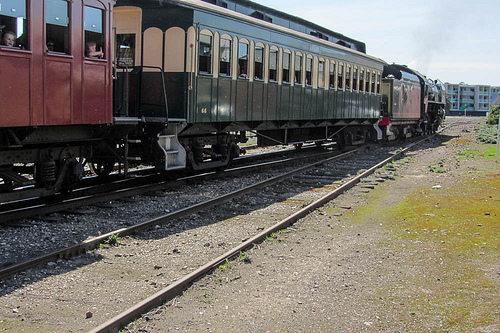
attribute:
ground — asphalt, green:
[230, 262, 303, 298]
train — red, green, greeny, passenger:
[200, 26, 339, 135]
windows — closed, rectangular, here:
[224, 37, 327, 68]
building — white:
[446, 90, 483, 112]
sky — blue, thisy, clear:
[386, 13, 448, 42]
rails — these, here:
[275, 10, 310, 40]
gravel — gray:
[174, 205, 216, 214]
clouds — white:
[437, 45, 472, 66]